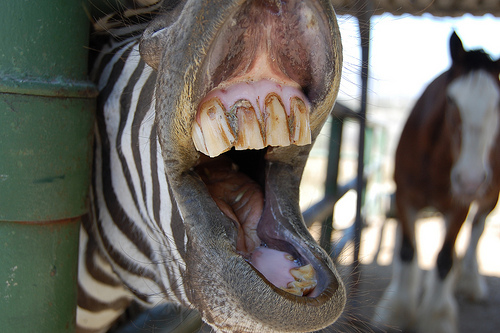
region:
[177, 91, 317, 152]
zebra's top teeth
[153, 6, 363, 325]
mouth is open on the zebra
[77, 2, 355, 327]
zebra with its mouth open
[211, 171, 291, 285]
the tongue of the zebra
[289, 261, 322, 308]
the bottom front teeth of the zebra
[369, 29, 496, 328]
a brown and white horse in the background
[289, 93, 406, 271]
metal gate next to the horse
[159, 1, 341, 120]
the top lip of the zebra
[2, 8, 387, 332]
the zebra is in a stable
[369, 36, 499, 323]
a clydsdale horse next to the zebra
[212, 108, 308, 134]
the teeth of a zebra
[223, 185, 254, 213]
the tongue of a zebra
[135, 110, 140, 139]
the black stripe of a zebra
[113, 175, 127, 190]
the white stripe of a zebra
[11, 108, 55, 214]
a green metal bar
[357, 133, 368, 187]
a metal bar int the background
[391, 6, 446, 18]
the edge of a shed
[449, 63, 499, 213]
the face of a horse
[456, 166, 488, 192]
the nose of a horse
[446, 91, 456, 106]
the eye of a horse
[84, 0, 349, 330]
open mouth of a zebra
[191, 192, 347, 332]
a zebra's bottom lip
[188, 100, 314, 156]
the teeth of a zebra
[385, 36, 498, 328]
brown and white horse standing off to the side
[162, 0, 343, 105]
top lip of a zebra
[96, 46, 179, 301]
black and white stripes on a zebra's face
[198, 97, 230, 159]
one tooth of a zebra with its mouth open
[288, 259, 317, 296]
a zebra's bottom teeth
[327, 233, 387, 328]
whiskers on a zebras bottom lip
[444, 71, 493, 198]
brown and white face of a horse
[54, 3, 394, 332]
a zebra with its mouth open with some gross yellow teeth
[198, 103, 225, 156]
a yellow zebra tooth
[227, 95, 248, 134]
a rotten zebra tooth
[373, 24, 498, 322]
a large brown and white horse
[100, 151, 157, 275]
some black and white zebra stripes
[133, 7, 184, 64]
a zebra nostril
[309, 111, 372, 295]
a metal fence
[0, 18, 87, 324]
a green metal bar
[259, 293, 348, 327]
a zebra lip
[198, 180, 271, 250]
a zebra tounge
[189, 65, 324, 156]
a zebras teeth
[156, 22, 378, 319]
a zebras open mouth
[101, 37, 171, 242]
black and white zebra stripes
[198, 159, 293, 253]
a zebra's pink tongue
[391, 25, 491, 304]
a brown and white horse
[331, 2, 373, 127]
a zebra's wiskers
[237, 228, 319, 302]
a zebras pink mouth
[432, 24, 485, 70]
a horses brown ear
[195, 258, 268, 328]
a zebras speckled lips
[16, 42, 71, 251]
a green and white building